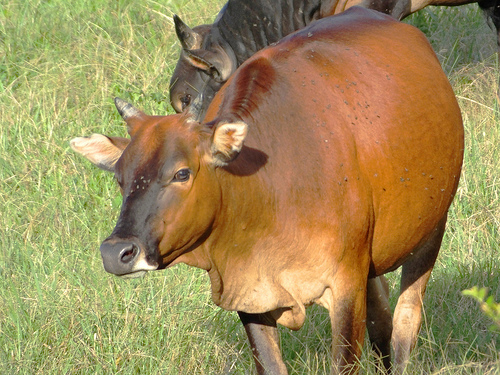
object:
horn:
[182, 91, 203, 126]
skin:
[243, 4, 323, 33]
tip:
[279, 314, 306, 331]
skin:
[343, 8, 461, 193]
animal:
[167, 0, 499, 115]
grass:
[0, 0, 122, 140]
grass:
[289, 317, 498, 373]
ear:
[199, 120, 250, 169]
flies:
[130, 172, 152, 192]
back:
[258, 4, 387, 82]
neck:
[218, 4, 285, 30]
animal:
[68, 6, 464, 375]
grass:
[30, 221, 84, 317]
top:
[169, 13, 187, 31]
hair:
[224, 126, 233, 151]